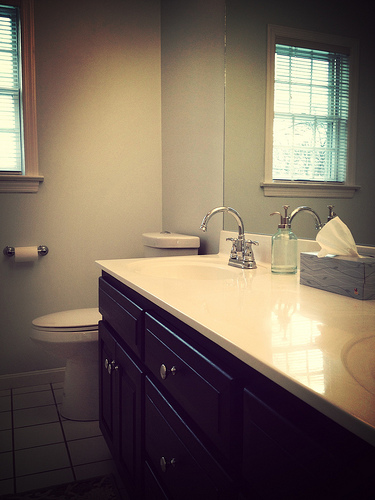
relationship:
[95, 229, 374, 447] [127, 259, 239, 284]
vanity has sink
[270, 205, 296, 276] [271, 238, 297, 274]
dispenser of soap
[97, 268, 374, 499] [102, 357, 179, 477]
cabinet has knobs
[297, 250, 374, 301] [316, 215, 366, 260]
box of tissue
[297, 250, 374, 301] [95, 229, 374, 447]
box on vanity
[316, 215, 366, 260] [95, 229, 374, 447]
tissue on vanity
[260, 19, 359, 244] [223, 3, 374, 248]
reflection in mirror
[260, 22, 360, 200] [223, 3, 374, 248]
window in mirror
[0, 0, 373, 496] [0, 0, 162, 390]
bathroom has wall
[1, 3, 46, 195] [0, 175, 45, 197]
window has sill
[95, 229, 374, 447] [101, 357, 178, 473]
vanity has hardware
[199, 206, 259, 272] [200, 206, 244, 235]
faucet has curve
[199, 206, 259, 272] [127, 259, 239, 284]
faucet over sink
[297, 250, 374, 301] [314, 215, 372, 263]
box has tissues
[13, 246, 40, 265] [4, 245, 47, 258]
toilet paper on holder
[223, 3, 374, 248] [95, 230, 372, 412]
mirror behind counter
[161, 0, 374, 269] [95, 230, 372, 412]
wall behind counter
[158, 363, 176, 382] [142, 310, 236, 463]
hardware on a drawer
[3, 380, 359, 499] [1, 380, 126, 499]
tile on floor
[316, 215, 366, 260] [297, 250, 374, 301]
tissue in a box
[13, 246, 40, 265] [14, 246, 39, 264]
toilet paper in roll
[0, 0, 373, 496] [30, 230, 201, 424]
bathroom has toilet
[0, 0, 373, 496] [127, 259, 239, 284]
bathroom has sink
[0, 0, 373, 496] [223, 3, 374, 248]
bathroom has mirror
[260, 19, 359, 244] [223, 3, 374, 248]
reflection of mirror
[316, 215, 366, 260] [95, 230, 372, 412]
tissue on counter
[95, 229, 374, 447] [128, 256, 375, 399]
counter top with sinks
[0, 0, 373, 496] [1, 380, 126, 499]
bathroom has floor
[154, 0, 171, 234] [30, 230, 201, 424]
corner behind toilet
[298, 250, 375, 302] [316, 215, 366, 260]
box has tissue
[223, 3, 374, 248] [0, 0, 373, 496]
mirror in bathroom